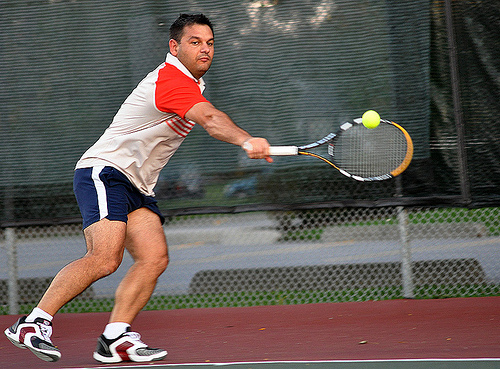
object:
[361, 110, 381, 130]
ball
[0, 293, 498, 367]
surface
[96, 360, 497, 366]
surface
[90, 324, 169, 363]
shoes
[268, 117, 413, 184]
racket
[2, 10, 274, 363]
man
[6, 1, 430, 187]
mesh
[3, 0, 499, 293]
fence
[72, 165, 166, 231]
shorts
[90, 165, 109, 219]
stripe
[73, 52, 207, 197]
shirt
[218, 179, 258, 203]
vehicle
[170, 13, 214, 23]
short hair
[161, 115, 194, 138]
stripes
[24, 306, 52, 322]
socks